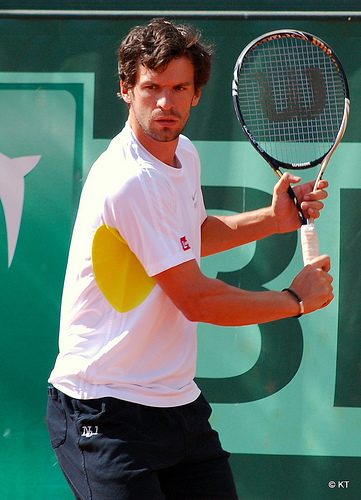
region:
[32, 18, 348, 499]
The man is playing tennis.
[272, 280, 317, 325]
The man has a bracelet on his wrist.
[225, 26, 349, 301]
The man is holding a tennis racket.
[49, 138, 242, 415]
The man is wearing a white shirt with yellow on it.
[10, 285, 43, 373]
Part of the wall is green.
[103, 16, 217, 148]
The man has brown hair.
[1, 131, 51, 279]
Part of the wall is white and green.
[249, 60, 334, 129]
A W is on the tennis racket.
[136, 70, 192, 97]
The man has two eyes.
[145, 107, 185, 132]
The man has a mouth.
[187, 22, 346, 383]
man holding a racquet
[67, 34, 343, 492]
man holding a racquet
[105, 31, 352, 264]
man holding a racquet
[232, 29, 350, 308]
black and white tennis rack in player's hands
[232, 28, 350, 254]
black, orange and white tennis racket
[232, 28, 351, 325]
Wilson's racket in tennis player's hands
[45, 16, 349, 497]
tennis player wearing a white t-shirt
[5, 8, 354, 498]
man playing a game of tennis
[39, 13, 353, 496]
tennis player on the court playing a game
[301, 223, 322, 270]
white handle on Wilson's tennis racket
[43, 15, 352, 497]
tennis player preparing to hit the ball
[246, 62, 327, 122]
Wilson's logo on net of tennis racket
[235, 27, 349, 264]
a tennis raquet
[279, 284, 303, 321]
a black bracelet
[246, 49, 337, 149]
the net on the raquet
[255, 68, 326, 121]
the w on the raquet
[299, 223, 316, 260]
handle of the raquet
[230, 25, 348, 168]
the upper rim of the racquet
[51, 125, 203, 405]
the mans white shirt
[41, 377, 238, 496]
the man's black bottoms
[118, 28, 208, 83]
the man's brown hair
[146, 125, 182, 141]
the man's chin hair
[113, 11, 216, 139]
the head of a man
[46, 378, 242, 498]
a pair of black pants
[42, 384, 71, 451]
a pocket on the pants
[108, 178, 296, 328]
the arm of a man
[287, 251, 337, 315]
the hand of a man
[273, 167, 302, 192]
the thumb of a man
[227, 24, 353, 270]
a black and white tennis racket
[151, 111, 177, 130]
the mouth of a man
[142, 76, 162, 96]
the eye of a man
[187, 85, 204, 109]
the ear of a man